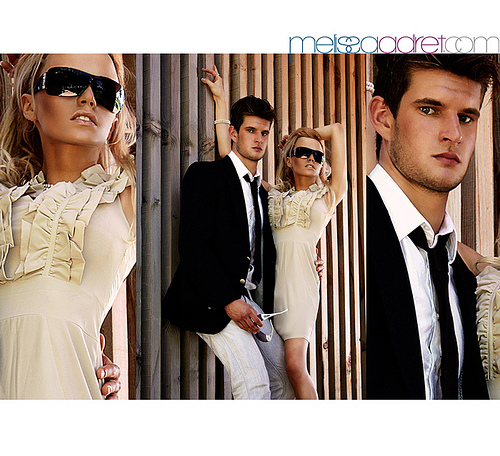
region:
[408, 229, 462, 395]
a long black tie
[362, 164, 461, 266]
a man's white shirt collar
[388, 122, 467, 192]
a man's beard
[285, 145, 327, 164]
dark black sunglasses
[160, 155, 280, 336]
a man's black sports coat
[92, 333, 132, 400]
the hand of a man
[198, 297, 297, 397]
men's white pants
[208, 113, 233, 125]
a diamond bracelet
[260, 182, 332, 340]
a woman's sleeveless beige dress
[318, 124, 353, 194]
the arm of a woman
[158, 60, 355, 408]
man holding a woman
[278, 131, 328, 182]
woman wearing black sunglasses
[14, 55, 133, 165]
woman wearing black sunglasses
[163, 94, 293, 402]
man holding sunglasses in his right hand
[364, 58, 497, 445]
man wearing a neck tie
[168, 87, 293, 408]
man wearing jeans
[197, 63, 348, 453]
woman wearing a biege dress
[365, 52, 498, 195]
man with an unshaven face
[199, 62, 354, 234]
woman wearing a silver bracelet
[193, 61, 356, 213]
woman with a ring on her finger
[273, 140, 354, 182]
the eyeglass is black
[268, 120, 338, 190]
the eyeglass is black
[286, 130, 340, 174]
the eyeglass is black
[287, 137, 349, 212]
the eyeglass is black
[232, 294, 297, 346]
man and woman leaning on wall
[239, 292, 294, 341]
sunglasses in man's hand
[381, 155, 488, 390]
man wearing a necktie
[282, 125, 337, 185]
woman wearing a pair of sunglasses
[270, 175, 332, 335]
woman wearing white dress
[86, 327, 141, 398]
man's hand on woman's waist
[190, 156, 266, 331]
man wearing black jacket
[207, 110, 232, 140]
bracelet on woman's wrist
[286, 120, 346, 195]
woman with blond hair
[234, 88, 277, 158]
man with dark hair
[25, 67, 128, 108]
this is a pair of sunglasses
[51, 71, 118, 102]
the sunglasses are dark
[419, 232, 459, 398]
this is a tie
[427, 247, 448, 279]
the tie is black in color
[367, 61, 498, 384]
this is a man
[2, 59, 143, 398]
this is a woman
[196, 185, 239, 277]
the coat is black in color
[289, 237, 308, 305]
the dress is white in color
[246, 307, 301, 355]
the man is holding sunglasses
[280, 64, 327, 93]
the wall is wooden